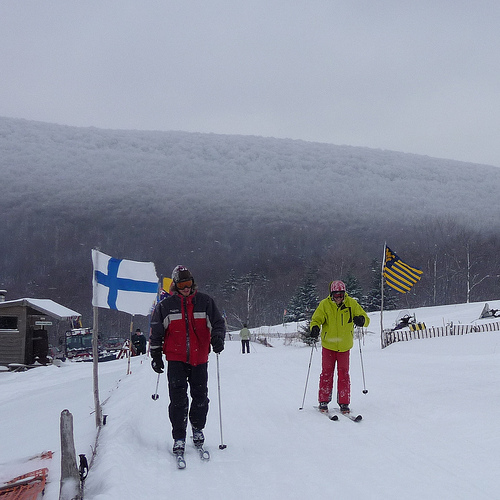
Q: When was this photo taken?
A: During the daytime.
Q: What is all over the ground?
A: Snow.